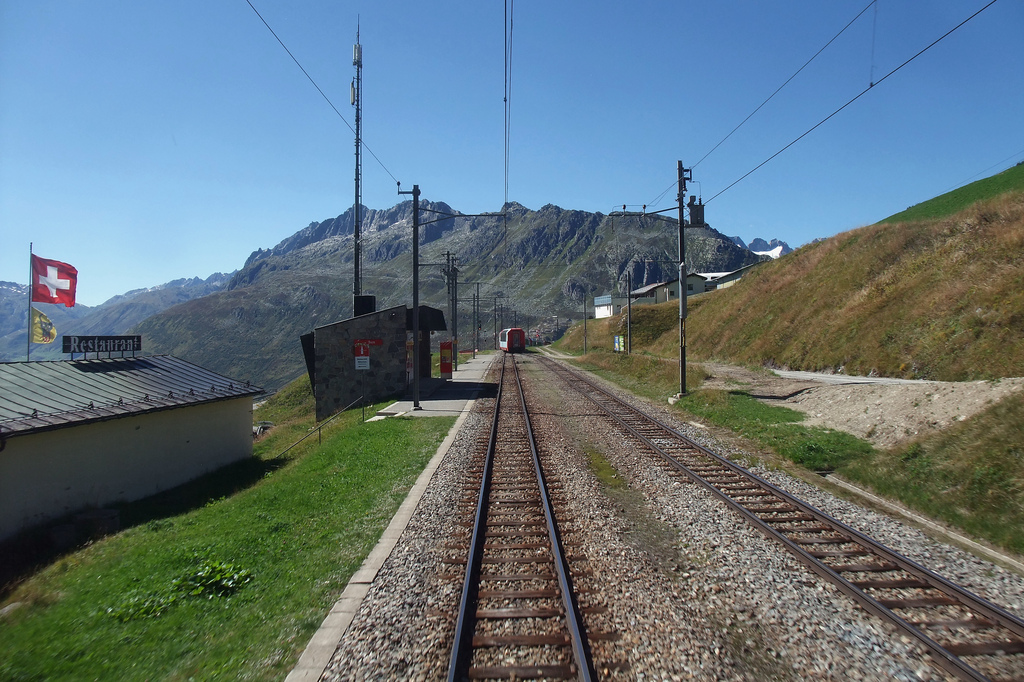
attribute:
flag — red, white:
[13, 247, 87, 371]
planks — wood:
[476, 582, 559, 650]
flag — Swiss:
[20, 246, 79, 363]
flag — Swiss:
[17, 240, 85, 359]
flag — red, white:
[19, 256, 78, 371]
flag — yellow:
[19, 246, 86, 361]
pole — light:
[662, 158, 701, 406]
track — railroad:
[449, 356, 595, 679]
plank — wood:
[485, 514, 552, 527]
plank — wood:
[468, 631, 582, 648]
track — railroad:
[465, 353, 593, 666]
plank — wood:
[459, 581, 564, 608]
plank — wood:
[797, 536, 865, 556]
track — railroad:
[437, 350, 609, 670]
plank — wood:
[465, 622, 577, 645]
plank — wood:
[473, 582, 559, 605]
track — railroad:
[520, 348, 1011, 677]